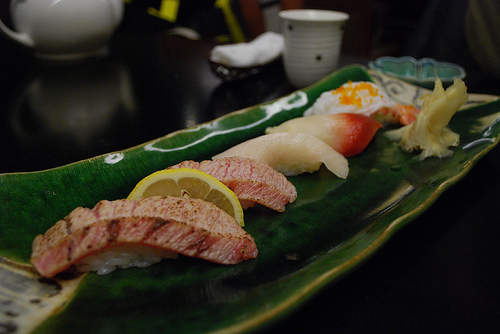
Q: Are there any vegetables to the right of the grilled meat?
A: Yes, there is a vegetable to the right of the meat.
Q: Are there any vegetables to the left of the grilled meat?
A: No, the vegetable is to the right of the meat.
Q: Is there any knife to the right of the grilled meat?
A: No, there is a vegetable to the right of the meat.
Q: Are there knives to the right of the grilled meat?
A: No, there is a vegetable to the right of the meat.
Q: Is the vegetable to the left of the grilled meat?
A: No, the vegetable is to the right of the meat.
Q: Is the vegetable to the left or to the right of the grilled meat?
A: The vegetable is to the right of the meat.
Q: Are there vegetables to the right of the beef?
A: Yes, there is a vegetable to the right of the beef.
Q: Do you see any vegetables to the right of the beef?
A: Yes, there is a vegetable to the right of the beef.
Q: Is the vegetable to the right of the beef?
A: Yes, the vegetable is to the right of the beef.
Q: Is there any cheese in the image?
A: Yes, there is cheese.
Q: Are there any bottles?
A: No, there are no bottles.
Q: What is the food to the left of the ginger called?
A: The food is cheese.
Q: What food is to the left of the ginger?
A: The food is cheese.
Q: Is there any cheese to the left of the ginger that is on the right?
A: Yes, there is cheese to the left of the ginger.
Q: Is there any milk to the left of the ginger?
A: No, there is cheese to the left of the ginger.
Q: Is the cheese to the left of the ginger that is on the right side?
A: Yes, the cheese is to the left of the ginger.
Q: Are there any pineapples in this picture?
A: Yes, there is a pineapple.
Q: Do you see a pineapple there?
A: Yes, there is a pineapple.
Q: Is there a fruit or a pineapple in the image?
A: Yes, there is a pineapple.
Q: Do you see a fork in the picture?
A: No, there are no forks.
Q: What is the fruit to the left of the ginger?
A: The fruit is a pineapple.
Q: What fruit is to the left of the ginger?
A: The fruit is a pineapple.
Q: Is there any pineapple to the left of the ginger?
A: Yes, there is a pineapple to the left of the ginger.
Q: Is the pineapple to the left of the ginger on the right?
A: Yes, the pineapple is to the left of the ginger.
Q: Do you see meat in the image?
A: Yes, there is meat.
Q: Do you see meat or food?
A: Yes, there is meat.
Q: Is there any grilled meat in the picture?
A: Yes, there is grilled meat.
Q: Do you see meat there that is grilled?
A: Yes, there is grilled meat.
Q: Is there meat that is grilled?
A: Yes, there is meat that is grilled.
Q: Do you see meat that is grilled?
A: Yes, there is meat that is grilled.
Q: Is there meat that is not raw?
A: Yes, there is grilled meat.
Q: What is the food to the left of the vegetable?
A: The food is meat.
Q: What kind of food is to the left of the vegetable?
A: The food is meat.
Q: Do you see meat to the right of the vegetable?
A: No, the meat is to the left of the vegetable.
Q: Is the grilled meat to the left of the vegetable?
A: Yes, the meat is to the left of the vegetable.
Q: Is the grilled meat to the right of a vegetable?
A: No, the meat is to the left of a vegetable.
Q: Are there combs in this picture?
A: No, there are no combs.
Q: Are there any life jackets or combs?
A: No, there are no combs or life jackets.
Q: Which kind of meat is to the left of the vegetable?
A: The meat is beef.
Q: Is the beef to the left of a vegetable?
A: Yes, the beef is to the left of a vegetable.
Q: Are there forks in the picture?
A: No, there are no forks.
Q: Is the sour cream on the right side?
A: Yes, the sour cream is on the right of the image.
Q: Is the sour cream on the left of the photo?
A: No, the sour cream is on the right of the image.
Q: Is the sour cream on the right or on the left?
A: The sour cream is on the right of the image.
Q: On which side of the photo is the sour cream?
A: The sour cream is on the right of the image.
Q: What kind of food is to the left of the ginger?
A: The food is sour cream.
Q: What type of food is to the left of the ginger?
A: The food is sour cream.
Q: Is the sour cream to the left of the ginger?
A: Yes, the sour cream is to the left of the ginger.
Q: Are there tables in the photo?
A: Yes, there is a table.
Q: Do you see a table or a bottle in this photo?
A: Yes, there is a table.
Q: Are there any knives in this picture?
A: No, there are no knives.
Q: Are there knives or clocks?
A: No, there are no knives or clocks.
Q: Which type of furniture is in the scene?
A: The furniture is a table.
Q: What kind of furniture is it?
A: The piece of furniture is a table.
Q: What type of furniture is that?
A: This is a table.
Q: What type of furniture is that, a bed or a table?
A: This is a table.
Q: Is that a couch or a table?
A: That is a table.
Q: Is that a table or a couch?
A: That is a table.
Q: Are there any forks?
A: No, there are no forks.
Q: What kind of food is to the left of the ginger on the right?
A: The food is shrimp.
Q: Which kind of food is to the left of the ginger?
A: The food is shrimp.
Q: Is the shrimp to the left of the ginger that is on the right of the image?
A: Yes, the shrimp is to the left of the ginger.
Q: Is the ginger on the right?
A: Yes, the ginger is on the right of the image.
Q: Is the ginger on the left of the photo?
A: No, the ginger is on the right of the image.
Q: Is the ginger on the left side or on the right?
A: The ginger is on the right of the image.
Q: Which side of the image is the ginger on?
A: The ginger is on the right of the image.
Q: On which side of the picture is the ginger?
A: The ginger is on the right of the image.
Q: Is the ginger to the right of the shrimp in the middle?
A: Yes, the ginger is to the right of the shrimp.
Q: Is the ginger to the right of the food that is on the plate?
A: Yes, the ginger is to the right of the food.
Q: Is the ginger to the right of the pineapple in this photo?
A: Yes, the ginger is to the right of the pineapple.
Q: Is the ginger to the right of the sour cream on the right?
A: Yes, the ginger is to the right of the sour cream.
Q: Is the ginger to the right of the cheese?
A: Yes, the ginger is to the right of the cheese.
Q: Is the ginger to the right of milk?
A: No, the ginger is to the right of the cheese.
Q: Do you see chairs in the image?
A: No, there are no chairs.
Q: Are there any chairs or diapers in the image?
A: No, there are no chairs or diapers.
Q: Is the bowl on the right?
A: Yes, the bowl is on the right of the image.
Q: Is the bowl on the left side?
A: No, the bowl is on the right of the image.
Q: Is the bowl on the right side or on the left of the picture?
A: The bowl is on the right of the image.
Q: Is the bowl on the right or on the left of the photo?
A: The bowl is on the right of the image.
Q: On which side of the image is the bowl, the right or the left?
A: The bowl is on the right of the image.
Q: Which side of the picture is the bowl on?
A: The bowl is on the right of the image.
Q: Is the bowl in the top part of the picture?
A: Yes, the bowl is in the top of the image.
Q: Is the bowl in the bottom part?
A: No, the bowl is in the top of the image.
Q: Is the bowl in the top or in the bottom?
A: The bowl is in the top of the image.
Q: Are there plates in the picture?
A: Yes, there is a plate.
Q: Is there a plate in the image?
A: Yes, there is a plate.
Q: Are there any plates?
A: Yes, there is a plate.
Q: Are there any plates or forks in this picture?
A: Yes, there is a plate.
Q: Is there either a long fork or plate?
A: Yes, there is a long plate.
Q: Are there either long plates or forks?
A: Yes, there is a long plate.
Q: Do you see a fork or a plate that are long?
A: Yes, the plate is long.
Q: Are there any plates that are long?
A: Yes, there is a long plate.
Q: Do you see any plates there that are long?
A: Yes, there is a plate that is long.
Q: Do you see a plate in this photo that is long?
A: Yes, there is a plate that is long.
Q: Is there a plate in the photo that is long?
A: Yes, there is a plate that is long.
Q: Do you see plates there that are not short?
A: Yes, there is a long plate.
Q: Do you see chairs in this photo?
A: No, there are no chairs.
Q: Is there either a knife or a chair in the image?
A: No, there are no chairs or knives.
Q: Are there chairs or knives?
A: No, there are no chairs or knives.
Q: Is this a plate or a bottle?
A: This is a plate.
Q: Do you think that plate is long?
A: Yes, the plate is long.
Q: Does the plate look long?
A: Yes, the plate is long.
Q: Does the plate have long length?
A: Yes, the plate is long.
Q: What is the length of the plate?
A: The plate is long.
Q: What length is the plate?
A: The plate is long.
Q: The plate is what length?
A: The plate is long.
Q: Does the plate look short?
A: No, the plate is long.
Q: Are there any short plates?
A: No, there is a plate but it is long.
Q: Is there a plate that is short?
A: No, there is a plate but it is long.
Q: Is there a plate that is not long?
A: No, there is a plate but it is long.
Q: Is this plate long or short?
A: The plate is long.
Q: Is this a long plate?
A: Yes, this is a long plate.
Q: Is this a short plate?
A: No, this is a long plate.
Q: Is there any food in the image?
A: Yes, there is food.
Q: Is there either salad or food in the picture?
A: Yes, there is food.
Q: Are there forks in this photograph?
A: No, there are no forks.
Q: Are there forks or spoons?
A: No, there are no forks or spoons.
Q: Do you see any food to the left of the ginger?
A: Yes, there is food to the left of the ginger.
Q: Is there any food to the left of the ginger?
A: Yes, there is food to the left of the ginger.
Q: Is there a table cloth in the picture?
A: No, there are no tablecloths.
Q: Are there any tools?
A: No, there are no tools.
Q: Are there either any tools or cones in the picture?
A: No, there are no tools or cones.